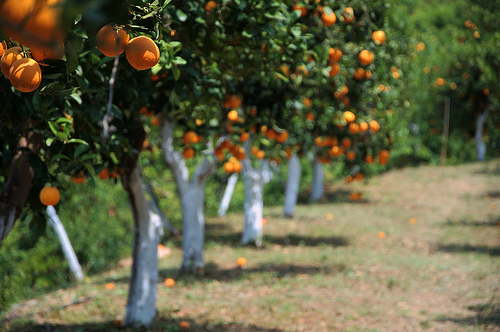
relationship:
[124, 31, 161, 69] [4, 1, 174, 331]
orange hanging in tree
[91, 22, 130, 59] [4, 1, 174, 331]
orange hanging in tree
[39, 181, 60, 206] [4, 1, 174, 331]
orange hanging in tree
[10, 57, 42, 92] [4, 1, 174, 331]
orange hanging in tree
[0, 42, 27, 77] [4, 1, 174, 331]
orange hanging in tree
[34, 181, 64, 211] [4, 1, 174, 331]
orange hanging in tree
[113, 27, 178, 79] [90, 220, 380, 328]
oranges on ground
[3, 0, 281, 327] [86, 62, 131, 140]
trees have branches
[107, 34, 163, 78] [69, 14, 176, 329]
fruits hanging from tree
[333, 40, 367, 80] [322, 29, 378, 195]
fruits hanging from tree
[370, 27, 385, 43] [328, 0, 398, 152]
fruit hanging from tree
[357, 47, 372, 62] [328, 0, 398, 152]
fruit hanging from tree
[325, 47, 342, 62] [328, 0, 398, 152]
fruit hanging from tree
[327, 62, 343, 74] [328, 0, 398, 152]
fruit hanging from tree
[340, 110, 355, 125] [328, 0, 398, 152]
fruit hanging from tree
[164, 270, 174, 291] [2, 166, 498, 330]
fruit on ground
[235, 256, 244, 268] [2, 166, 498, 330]
fruit on ground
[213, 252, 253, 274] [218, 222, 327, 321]
fruits on ground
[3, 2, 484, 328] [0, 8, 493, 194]
trees have oranges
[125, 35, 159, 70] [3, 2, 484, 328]
orange on trees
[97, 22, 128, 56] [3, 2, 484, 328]
orange on trees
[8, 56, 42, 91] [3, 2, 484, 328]
orange on trees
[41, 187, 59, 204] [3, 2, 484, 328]
orange on trees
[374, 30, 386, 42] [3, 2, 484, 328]
orange on trees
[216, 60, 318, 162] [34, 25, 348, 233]
trees in line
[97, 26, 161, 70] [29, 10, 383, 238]
oranges growing on trees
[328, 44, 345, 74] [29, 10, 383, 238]
oranges growing on trees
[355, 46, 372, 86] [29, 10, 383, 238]
oranges growing on trees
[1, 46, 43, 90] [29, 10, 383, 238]
oranges growing on trees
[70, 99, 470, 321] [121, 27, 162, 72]
tree leaves have oranges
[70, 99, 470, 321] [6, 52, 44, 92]
tree leaves have oranges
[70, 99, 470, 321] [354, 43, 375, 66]
tree leaves have oranges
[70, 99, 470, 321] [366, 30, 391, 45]
tree leaves have oranges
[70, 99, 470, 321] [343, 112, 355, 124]
tree leaves have oranges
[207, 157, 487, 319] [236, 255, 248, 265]
ground has orange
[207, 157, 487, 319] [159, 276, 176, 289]
ground has orange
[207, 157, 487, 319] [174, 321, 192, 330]
ground has orange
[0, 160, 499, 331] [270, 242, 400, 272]
ground has grass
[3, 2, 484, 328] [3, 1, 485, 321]
trees in garden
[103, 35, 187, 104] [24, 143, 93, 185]
orange on branch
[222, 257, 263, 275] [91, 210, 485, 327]
orange on ground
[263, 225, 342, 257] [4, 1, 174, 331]
shadow of tree